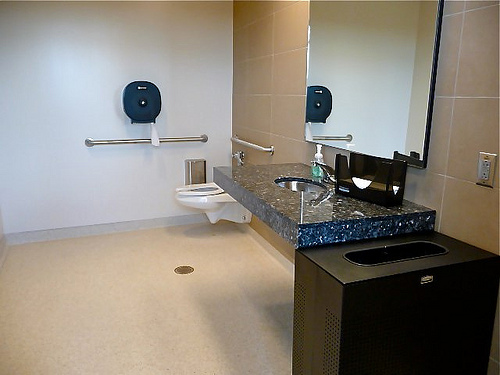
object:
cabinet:
[291, 229, 498, 375]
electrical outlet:
[476, 151, 499, 187]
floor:
[0, 223, 293, 375]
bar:
[84, 133, 208, 148]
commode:
[174, 151, 254, 225]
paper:
[150, 122, 160, 147]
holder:
[122, 81, 162, 125]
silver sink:
[273, 177, 326, 193]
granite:
[212, 162, 437, 249]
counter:
[212, 162, 437, 250]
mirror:
[304, 0, 443, 170]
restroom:
[0, 0, 500, 375]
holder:
[334, 151, 407, 207]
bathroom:
[0, 0, 500, 375]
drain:
[173, 265, 196, 276]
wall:
[0, 0, 238, 236]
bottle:
[310, 144, 325, 179]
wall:
[228, 0, 500, 290]